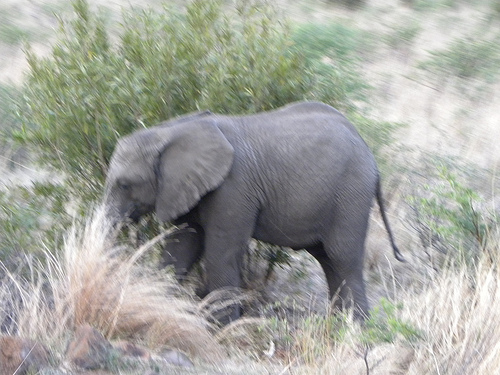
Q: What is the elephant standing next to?
A: A bush.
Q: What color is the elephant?
A: Grey.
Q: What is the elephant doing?
A: Standing.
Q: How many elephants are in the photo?
A: One.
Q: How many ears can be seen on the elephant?
A: One.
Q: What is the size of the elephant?
A: Small.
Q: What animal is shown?
A: Elephant.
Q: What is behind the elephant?
A: A tree.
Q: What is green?
A: The trees.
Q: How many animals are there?
A: One.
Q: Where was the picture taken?
A: In open landscape.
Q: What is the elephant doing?
A: Walking.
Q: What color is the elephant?
A: Gray.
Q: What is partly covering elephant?
A: Tall grass.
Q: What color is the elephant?
A: Gray.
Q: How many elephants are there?
A: One.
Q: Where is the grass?
A: Around the elephant.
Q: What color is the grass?
A: Yellow.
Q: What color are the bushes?
A: Green.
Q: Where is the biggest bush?
A: Behind the elephant.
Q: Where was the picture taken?
A: In an area of tall grass.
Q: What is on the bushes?
A: Small leaves.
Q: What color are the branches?
A: Brown.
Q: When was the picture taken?
A: Daytime.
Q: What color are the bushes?
A: Green.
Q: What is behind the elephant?
A: A bush.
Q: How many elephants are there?
A: One.